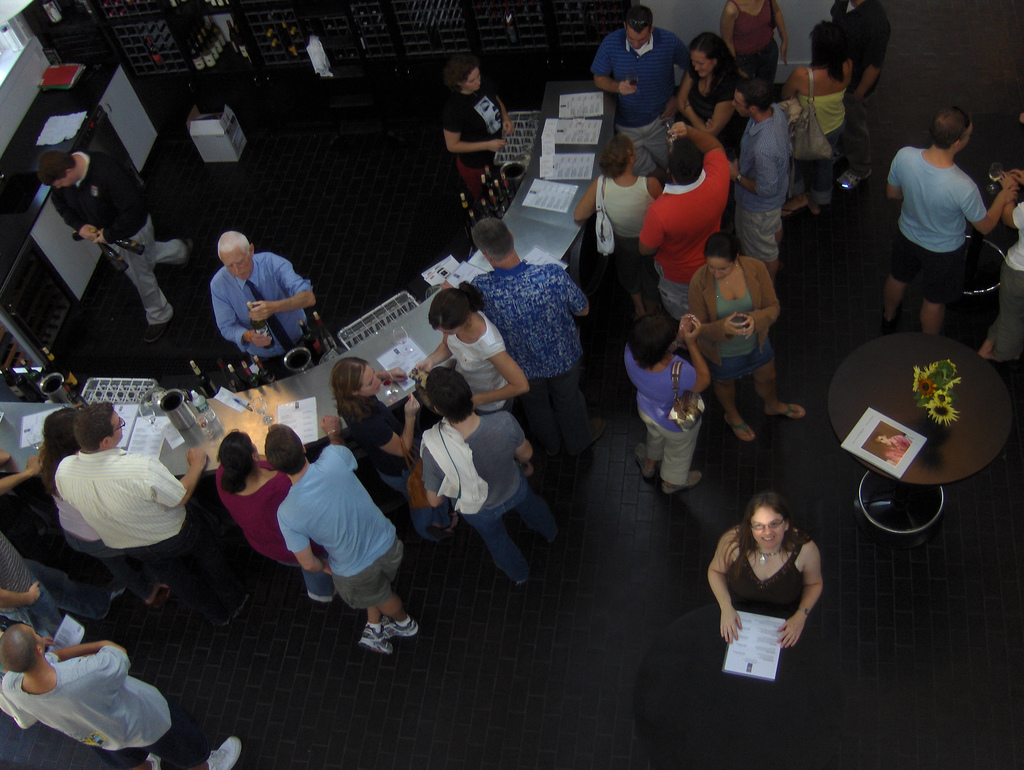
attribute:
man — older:
[203, 227, 326, 371]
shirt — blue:
[208, 250, 314, 360]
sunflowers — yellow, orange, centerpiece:
[907, 355, 965, 434]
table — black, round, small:
[825, 331, 1018, 554]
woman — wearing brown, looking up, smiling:
[705, 490, 827, 653]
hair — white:
[216, 229, 250, 257]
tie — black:
[247, 275, 296, 358]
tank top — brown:
[724, 525, 809, 618]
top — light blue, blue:
[276, 441, 402, 583]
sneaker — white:
[355, 621, 397, 659]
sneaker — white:
[377, 615, 419, 639]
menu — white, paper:
[720, 605, 790, 682]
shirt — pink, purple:
[213, 457, 309, 565]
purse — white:
[590, 172, 620, 260]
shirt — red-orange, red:
[638, 146, 733, 290]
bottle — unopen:
[486, 187, 504, 217]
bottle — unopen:
[462, 198, 483, 245]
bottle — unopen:
[457, 190, 475, 246]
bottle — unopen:
[489, 171, 509, 214]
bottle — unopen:
[474, 171, 490, 206]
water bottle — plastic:
[185, 387, 224, 446]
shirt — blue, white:
[469, 257, 591, 380]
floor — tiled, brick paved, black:
[8, 5, 1021, 768]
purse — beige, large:
[666, 356, 709, 437]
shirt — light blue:
[886, 135, 986, 260]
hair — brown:
[730, 486, 811, 579]